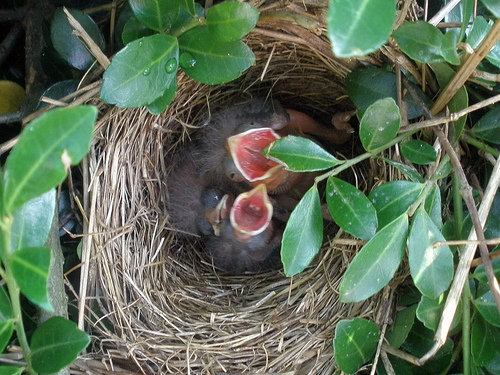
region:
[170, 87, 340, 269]
Young birds with mouth open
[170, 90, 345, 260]
Young birds wanting some food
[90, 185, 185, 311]
Nesting material in a bird nest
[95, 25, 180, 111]
Leaf with drops of water on it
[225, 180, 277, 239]
Open mouth of a bird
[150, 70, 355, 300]
Birds in a nest looking for a meal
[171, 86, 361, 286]
Newly hatched birds in a nest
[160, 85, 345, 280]
Hungry wild birds in a nest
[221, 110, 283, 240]
To hungry birds with open mouths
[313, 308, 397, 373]
Leaf alongside birds nest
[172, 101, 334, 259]
baby birds in nest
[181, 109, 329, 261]
hungry baby birds with beaks open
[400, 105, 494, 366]
plants with green leaves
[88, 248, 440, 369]
edge of a bird's nest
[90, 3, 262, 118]
dew drops on green leaves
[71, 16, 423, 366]
nest of baby birds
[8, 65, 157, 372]
green foliage beside bird's nest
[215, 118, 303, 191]
inside of a baby bird's mouth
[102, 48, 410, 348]
baby birds yelling for food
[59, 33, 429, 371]
small nest with baby birds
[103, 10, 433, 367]
three baby chicks in a nest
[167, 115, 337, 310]
the baby chicks are gray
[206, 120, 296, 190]
the mouth of the baby chick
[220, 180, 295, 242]
the mouth of the baby chick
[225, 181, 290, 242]
the mouth is open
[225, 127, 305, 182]
the mouth is open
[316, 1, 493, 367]
leaves around the nest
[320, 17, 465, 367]
the leaves are green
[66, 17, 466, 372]
The nest is made of straw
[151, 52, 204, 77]
water droplets on the leaves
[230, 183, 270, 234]
a baby birds mouth wide open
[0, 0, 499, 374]
a birds nest with three baby birds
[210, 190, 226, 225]
the birds yellow beak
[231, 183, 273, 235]
the birds yellow rim around the beak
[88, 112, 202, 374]
straw hay around the nest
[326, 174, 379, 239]
green leaf over the nest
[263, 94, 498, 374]
tree branch over the nest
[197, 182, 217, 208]
a baby birds eyeball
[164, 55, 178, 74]
a water droplet on the leaf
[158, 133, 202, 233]
a baby birds wing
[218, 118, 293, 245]
two demanding baby birds, open mouthed, in nest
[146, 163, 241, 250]
one quiet, sleepy baby bird in nest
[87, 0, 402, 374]
nest is finely constructed, largely from straw w/ the occasional twig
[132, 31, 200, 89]
rain droplets on leaves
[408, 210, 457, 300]
bird droplet on leaf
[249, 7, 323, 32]
green twig @ top of nest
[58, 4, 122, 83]
pointy twig sticks away from nest, upper left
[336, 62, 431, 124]
one dark green leave amid several forest green leaves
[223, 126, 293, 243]
inner birds' demanding jaws are bright pinky red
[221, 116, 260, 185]
bird has tiny, pinpoint black eyes, in seated search of food